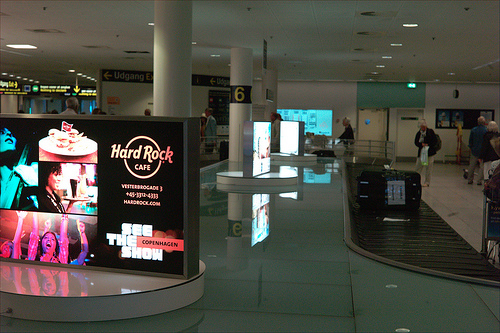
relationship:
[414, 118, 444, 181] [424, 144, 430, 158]
person holds a white bag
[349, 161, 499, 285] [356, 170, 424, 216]
conveyor belt for luggage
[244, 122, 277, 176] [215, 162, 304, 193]
sign on a podium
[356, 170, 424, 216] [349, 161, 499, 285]
luggage on conveyor belt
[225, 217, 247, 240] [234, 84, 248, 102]
reflection of number 6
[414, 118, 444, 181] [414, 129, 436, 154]
person wears a black coat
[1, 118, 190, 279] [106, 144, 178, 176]
sign for hard rock cafe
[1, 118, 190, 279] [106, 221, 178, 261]
sign for see the show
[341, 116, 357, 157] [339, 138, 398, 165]
person leans on a railing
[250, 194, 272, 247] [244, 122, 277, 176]
reflection of sign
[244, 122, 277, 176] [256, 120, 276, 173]
sign for advertising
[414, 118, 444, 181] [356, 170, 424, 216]
person waits for luggage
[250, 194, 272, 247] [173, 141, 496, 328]
reflection on floor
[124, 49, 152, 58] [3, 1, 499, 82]
vent in ceiling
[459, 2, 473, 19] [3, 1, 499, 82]
sprinkler in ceiling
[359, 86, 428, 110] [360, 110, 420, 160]
awning above doors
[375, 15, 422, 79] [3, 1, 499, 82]
lights on ceiling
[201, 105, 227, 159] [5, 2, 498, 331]
people in airport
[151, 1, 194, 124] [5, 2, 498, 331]
pole in airport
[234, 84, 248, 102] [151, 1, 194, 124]
6 on pole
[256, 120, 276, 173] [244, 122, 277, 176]
advertising has words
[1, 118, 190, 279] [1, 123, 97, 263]
sign has pictures